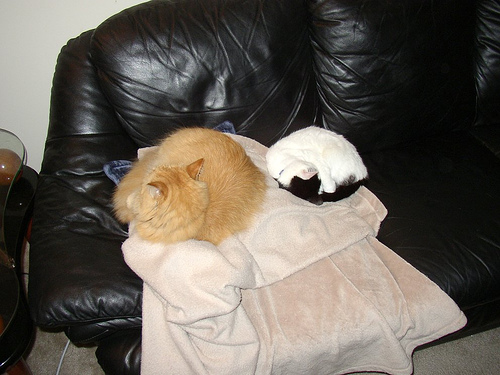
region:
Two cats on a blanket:
[116, 123, 373, 238]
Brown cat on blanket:
[117, 124, 266, 237]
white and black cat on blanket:
[262, 121, 369, 208]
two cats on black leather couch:
[31, 6, 497, 373]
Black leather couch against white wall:
[33, 3, 498, 372]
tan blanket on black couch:
[111, 126, 467, 373]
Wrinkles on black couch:
[97, 29, 322, 161]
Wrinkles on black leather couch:
[96, 18, 373, 163]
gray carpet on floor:
[418, 332, 498, 369]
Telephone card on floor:
[57, 336, 70, 371]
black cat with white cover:
[267, 120, 367, 205]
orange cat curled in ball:
[105, 120, 265, 241]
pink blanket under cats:
[117, 122, 462, 367]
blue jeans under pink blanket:
[91, 115, 241, 200]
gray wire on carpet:
[46, 327, 76, 372]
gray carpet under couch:
[10, 176, 495, 368]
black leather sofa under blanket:
[26, 0, 493, 370]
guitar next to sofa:
[0, 160, 45, 372]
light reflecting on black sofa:
[45, 31, 220, 147]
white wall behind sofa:
[1, 0, 156, 177]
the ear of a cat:
[183, 151, 212, 180]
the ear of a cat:
[145, 174, 175, 209]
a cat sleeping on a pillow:
[268, 125, 368, 207]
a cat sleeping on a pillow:
[108, 127, 266, 244]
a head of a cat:
[135, 156, 215, 223]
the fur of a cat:
[225, 152, 245, 192]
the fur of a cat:
[316, 137, 339, 155]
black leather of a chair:
[61, 155, 104, 212]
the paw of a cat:
[321, 172, 338, 198]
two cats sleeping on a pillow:
[108, 114, 375, 253]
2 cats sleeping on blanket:
[103, 116, 374, 244]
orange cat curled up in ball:
[104, 121, 265, 247]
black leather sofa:
[36, 0, 498, 373]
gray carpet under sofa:
[20, 233, 499, 373]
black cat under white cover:
[262, 117, 369, 202]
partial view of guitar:
[0, 159, 57, 371]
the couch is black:
[403, 75, 478, 256]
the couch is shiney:
[116, 53, 253, 106]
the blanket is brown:
[249, 274, 376, 326]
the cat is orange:
[115, 96, 267, 256]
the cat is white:
[263, 120, 370, 205]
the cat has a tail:
[320, 175, 363, 202]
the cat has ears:
[143, 159, 210, 196]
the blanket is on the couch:
[149, 270, 453, 322]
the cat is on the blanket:
[259, 128, 372, 210]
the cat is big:
[96, 124, 270, 249]